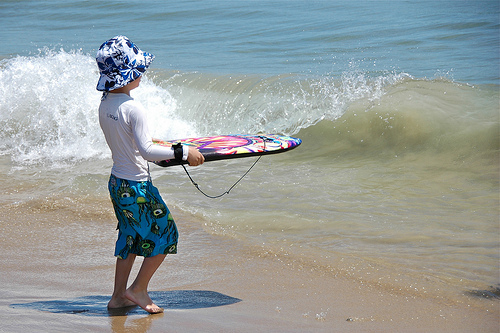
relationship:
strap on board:
[166, 141, 186, 165] [151, 132, 302, 197]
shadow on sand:
[10, 278, 247, 319] [5, 152, 498, 330]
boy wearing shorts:
[95, 36, 206, 315] [102, 172, 180, 255]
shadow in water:
[441, 283, 484, 312] [224, 41, 487, 297]